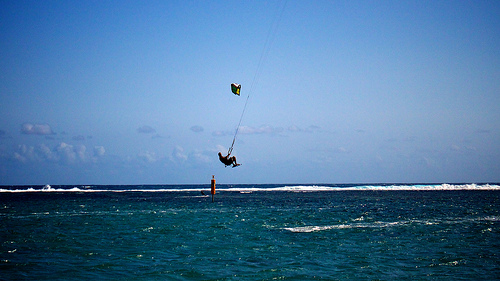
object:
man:
[217, 152, 242, 168]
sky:
[0, 0, 500, 184]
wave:
[0, 183, 499, 190]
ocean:
[0, 186, 500, 281]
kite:
[231, 82, 242, 96]